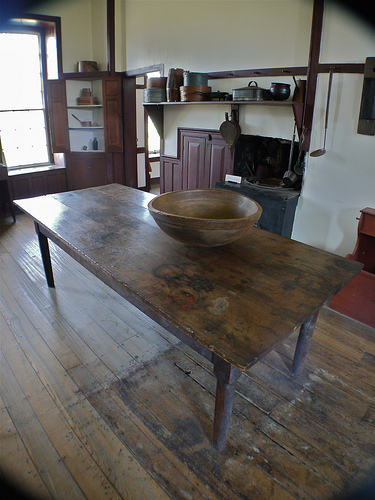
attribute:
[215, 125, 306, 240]
stove — black , old 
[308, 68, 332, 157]
ladle — gray, brown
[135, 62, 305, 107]
pots — assorted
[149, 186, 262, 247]
bowl — Giant 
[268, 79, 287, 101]
black cauldron — SMALL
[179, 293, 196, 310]
paint — red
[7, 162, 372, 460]
table — LARGE, brown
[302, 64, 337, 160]
spoon — wooden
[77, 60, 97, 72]
pot — old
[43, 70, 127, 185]
doors — FURNITURE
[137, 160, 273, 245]
bowl — WOODEN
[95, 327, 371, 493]
damaged floor — old, wooden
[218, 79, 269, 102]
container — METAL